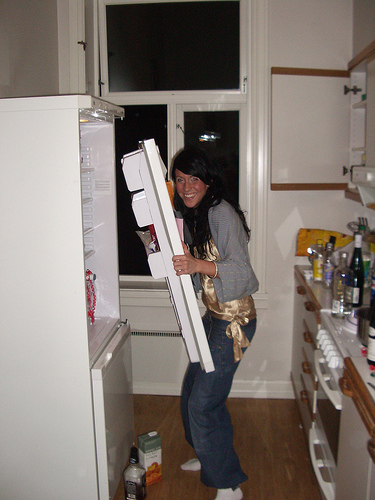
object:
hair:
[167, 145, 253, 263]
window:
[116, 104, 237, 276]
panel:
[166, 103, 183, 180]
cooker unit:
[303, 308, 369, 498]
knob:
[326, 357, 339, 370]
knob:
[324, 351, 334, 364]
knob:
[323, 343, 337, 363]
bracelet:
[206, 256, 220, 280]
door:
[117, 135, 220, 375]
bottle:
[311, 237, 324, 288]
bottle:
[321, 242, 334, 289]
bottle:
[332, 251, 355, 324]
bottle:
[345, 229, 365, 310]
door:
[266, 55, 367, 210]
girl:
[165, 143, 266, 500]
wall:
[246, 0, 375, 401]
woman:
[162, 145, 258, 498]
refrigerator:
[0, 94, 143, 500]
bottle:
[122, 444, 145, 499]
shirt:
[173, 195, 268, 324]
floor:
[100, 391, 329, 498]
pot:
[356, 303, 372, 351]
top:
[324, 240, 334, 253]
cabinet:
[282, 263, 375, 499]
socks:
[179, 456, 201, 475]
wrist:
[199, 261, 211, 274]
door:
[87, 319, 142, 500]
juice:
[138, 429, 164, 488]